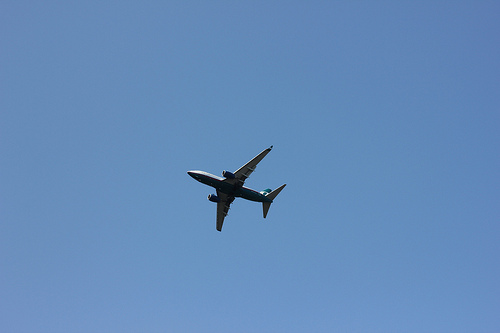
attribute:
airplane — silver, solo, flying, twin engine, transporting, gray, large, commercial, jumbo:
[183, 139, 289, 235]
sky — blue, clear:
[2, 2, 500, 332]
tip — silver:
[185, 170, 201, 178]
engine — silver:
[220, 172, 238, 179]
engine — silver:
[207, 193, 218, 202]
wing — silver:
[221, 141, 274, 184]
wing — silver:
[213, 188, 236, 231]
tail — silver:
[257, 184, 288, 216]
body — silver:
[196, 172, 269, 203]